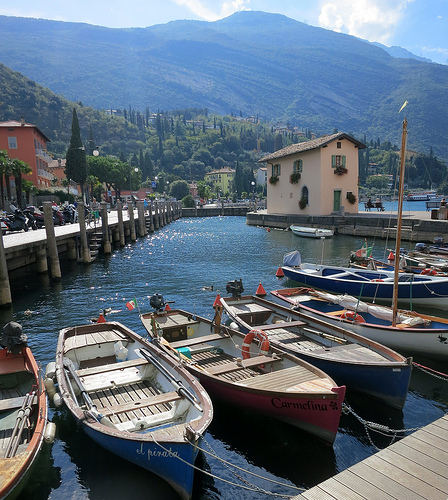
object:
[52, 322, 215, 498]
boat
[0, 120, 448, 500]
dock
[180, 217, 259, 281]
water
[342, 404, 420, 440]
ropes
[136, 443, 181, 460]
writing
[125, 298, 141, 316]
flag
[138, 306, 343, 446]
boat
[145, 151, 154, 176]
trees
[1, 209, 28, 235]
motorcycle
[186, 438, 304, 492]
rope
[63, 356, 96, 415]
oar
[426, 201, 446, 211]
bench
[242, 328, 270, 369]
life preserver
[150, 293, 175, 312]
motor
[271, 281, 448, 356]
boat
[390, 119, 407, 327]
mast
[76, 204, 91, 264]
pilings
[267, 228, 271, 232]
buoy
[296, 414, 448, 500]
deck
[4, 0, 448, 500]
island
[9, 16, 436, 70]
distant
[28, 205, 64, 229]
bike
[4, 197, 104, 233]
group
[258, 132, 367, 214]
building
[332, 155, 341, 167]
window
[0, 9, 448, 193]
mountain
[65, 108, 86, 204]
tree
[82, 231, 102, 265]
stairs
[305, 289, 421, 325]
sail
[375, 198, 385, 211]
people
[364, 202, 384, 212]
bench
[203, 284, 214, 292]
duck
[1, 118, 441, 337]
town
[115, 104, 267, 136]
home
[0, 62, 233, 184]
slope